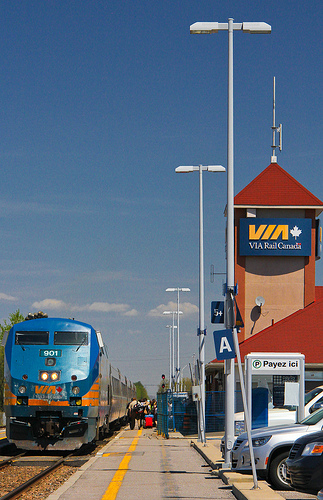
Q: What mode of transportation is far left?
A: A blue train.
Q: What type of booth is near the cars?
A: A parking pay booth.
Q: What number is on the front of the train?
A: 901.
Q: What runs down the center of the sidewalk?
A: A yellow divider line.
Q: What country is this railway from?
A: Canada.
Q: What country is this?
A: Canada.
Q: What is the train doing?
A: Sitting on the track.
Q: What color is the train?
A: Blue.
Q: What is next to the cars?
A: A building.